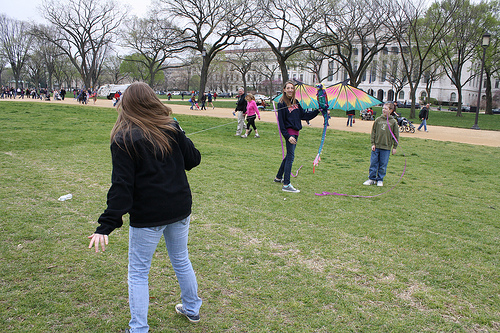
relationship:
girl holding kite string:
[83, 80, 203, 332] [184, 99, 320, 152]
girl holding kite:
[276, 77, 331, 195] [272, 71, 384, 177]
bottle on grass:
[56, 190, 79, 208] [3, 99, 499, 331]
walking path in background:
[3, 90, 499, 164] [2, 1, 497, 150]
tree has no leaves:
[149, 3, 267, 108] [150, 1, 265, 55]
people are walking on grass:
[234, 87, 264, 138] [3, 99, 499, 331]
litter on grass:
[56, 190, 79, 208] [3, 99, 499, 331]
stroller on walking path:
[393, 115, 416, 136] [3, 90, 499, 164]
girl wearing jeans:
[83, 80, 203, 332] [121, 217, 204, 331]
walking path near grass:
[3, 90, 499, 164] [3, 99, 499, 331]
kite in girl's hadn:
[272, 71, 384, 177] [317, 105, 329, 115]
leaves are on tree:
[405, 0, 499, 78] [407, 1, 499, 116]